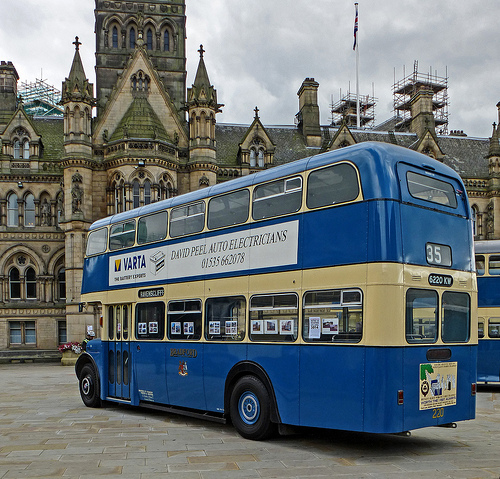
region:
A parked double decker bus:
[70, 133, 481, 450]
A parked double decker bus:
[71, 138, 479, 440]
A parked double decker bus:
[70, 137, 485, 445]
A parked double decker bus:
[66, 135, 479, 441]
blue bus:
[68, 131, 463, 478]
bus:
[48, 148, 472, 425]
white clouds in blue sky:
[232, 9, 272, 54]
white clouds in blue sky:
[251, 46, 276, 88]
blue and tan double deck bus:
[67, 115, 481, 442]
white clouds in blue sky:
[210, 15, 271, 52]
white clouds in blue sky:
[254, 16, 332, 71]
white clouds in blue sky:
[5, 11, 69, 62]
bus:
[42, 175, 482, 445]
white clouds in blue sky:
[237, 3, 331, 65]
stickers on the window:
[167, 315, 200, 337]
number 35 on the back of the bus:
[425, 241, 451, 266]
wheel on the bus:
[229, 371, 271, 442]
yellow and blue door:
[100, 307, 134, 401]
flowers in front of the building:
[55, 333, 80, 368]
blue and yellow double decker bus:
[62, 133, 487, 454]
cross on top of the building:
[240, 100, 267, 122]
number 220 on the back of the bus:
[422, 403, 454, 424]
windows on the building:
[2, 319, 44, 347]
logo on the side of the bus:
[165, 345, 200, 387]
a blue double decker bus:
[45, 140, 470, 451]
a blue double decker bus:
[52, 123, 470, 475]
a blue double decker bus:
[39, 154, 438, 476]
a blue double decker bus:
[78, 118, 418, 473]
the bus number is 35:
[420, 219, 460, 285]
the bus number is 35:
[414, 220, 459, 279]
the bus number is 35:
[412, 231, 459, 282]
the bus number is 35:
[411, 238, 458, 288]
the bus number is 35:
[408, 230, 453, 290]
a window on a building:
[10, 136, 19, 160]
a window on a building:
[2, 317, 21, 348]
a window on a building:
[21, 315, 35, 347]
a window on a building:
[7, 267, 22, 299]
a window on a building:
[25, 265, 39, 307]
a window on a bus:
[133, 300, 163, 337]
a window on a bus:
[157, 295, 199, 337]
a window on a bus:
[206, 300, 251, 336]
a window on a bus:
[301, 286, 362, 343]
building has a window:
[23, 191, 35, 226]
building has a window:
[8, 191, 19, 223]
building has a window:
[9, 264, 21, 296]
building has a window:
[23, 319, 38, 344]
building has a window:
[11, 320, 21, 345]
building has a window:
[13, 136, 21, 158]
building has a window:
[21, 139, 31, 159]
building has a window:
[133, 176, 138, 202]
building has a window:
[144, 176, 149, 203]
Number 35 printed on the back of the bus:
[426, 242, 443, 262]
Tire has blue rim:
[226, 370, 274, 440]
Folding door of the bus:
[106, 300, 129, 399]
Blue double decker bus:
[73, 137, 480, 440]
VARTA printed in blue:
[121, 252, 148, 271]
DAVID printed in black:
[169, 245, 190, 260]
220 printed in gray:
[430, 405, 445, 418]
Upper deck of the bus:
[75, 138, 477, 294]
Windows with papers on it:
[134, 284, 365, 345]